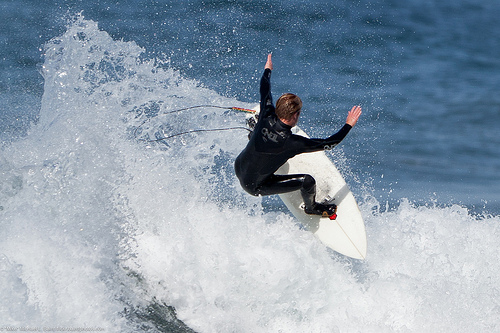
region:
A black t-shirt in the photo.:
[238, 120, 295, 187]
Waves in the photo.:
[210, 223, 293, 308]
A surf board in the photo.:
[313, 227, 370, 262]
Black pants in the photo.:
[271, 172, 317, 208]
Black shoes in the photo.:
[299, 202, 338, 217]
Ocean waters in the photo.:
[397, 142, 480, 194]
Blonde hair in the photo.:
[275, 88, 302, 125]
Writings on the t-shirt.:
[252, 122, 285, 144]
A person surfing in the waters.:
[230, 48, 365, 226]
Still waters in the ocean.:
[424, 12, 493, 94]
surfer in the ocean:
[221, 38, 385, 271]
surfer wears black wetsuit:
[224, 45, 371, 230]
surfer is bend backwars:
[210, 45, 380, 227]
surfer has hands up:
[226, 42, 373, 226]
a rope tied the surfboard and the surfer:
[134, 71, 271, 151]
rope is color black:
[123, 96, 262, 148]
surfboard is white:
[239, 103, 376, 270]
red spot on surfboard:
[305, 191, 350, 234]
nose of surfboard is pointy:
[336, 225, 376, 270]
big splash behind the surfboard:
[0, 0, 273, 307]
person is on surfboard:
[228, 45, 345, 217]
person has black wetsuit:
[245, 67, 325, 224]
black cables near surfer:
[137, 93, 287, 143]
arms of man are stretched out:
[245, 63, 317, 145]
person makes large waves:
[200, 84, 375, 249]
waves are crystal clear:
[35, 37, 273, 252]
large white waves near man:
[137, 195, 445, 307]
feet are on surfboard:
[283, 150, 353, 205]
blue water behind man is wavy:
[353, 22, 470, 137]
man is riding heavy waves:
[189, 216, 485, 331]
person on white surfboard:
[220, 106, 362, 280]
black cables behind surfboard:
[117, 75, 247, 152]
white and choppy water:
[2, 11, 176, 273]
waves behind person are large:
[20, 110, 220, 332]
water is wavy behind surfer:
[318, 40, 466, 172]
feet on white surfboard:
[269, 147, 360, 264]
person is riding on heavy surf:
[2, 137, 358, 332]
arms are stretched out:
[227, 37, 395, 193]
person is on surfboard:
[169, 62, 401, 252]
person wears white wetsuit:
[237, 84, 354, 233]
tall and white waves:
[32, 67, 481, 320]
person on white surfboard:
[269, 124, 389, 261]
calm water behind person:
[340, 17, 462, 177]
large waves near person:
[48, 136, 333, 286]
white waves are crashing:
[44, 142, 342, 314]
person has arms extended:
[247, 52, 414, 207]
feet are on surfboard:
[231, 103, 377, 253]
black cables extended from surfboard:
[120, 107, 299, 184]